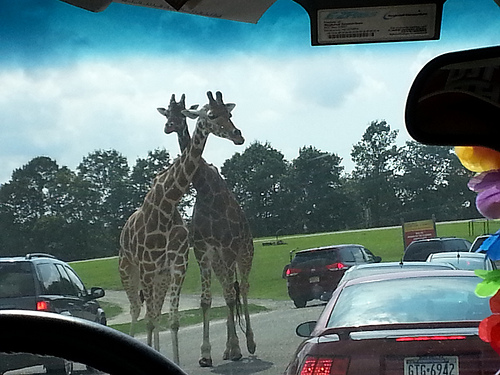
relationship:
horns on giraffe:
[202, 89, 214, 104] [117, 90, 248, 367]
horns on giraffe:
[212, 89, 223, 106] [117, 90, 248, 367]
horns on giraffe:
[165, 93, 176, 108] [158, 93, 256, 365]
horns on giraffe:
[177, 92, 187, 105] [158, 93, 256, 365]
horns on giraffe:
[204, 89, 215, 104] [161, 98, 281, 363]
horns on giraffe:
[180, 94, 188, 106] [126, 88, 246, 349]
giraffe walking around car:
[147, 103, 247, 208] [312, 267, 499, 369]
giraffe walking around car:
[158, 93, 258, 365] [312, 267, 499, 369]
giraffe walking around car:
[147, 103, 247, 208] [3, 250, 108, 349]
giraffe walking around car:
[158, 93, 258, 365] [3, 250, 108, 349]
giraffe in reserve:
[117, 90, 248, 367] [31, 86, 471, 305]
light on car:
[285, 266, 291, 275] [284, 242, 390, 303]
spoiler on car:
[317, 322, 486, 341] [282, 268, 497, 373]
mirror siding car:
[372, 255, 382, 262] [325, 277, 497, 373]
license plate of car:
[401, 350, 463, 374] [277, 256, 498, 374]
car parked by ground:
[285, 241, 384, 308] [119, 297, 332, 375]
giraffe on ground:
[158, 93, 256, 365] [119, 297, 332, 375]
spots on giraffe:
[140, 220, 185, 270] [117, 90, 248, 367]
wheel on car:
[280, 289, 314, 319] [276, 207, 391, 311]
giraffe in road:
[158, 93, 258, 365] [218, 320, 290, 367]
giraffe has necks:
[117, 90, 248, 367] [145, 130, 229, 205]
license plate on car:
[401, 350, 463, 374] [282, 260, 498, 367]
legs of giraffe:
[121, 285, 181, 367] [117, 90, 248, 367]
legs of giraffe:
[195, 259, 259, 366] [158, 93, 256, 365]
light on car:
[299, 353, 339, 371] [292, 258, 499, 372]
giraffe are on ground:
[117, 90, 248, 367] [119, 297, 332, 375]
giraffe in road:
[158, 93, 258, 365] [98, 290, 324, 369]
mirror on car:
[88, 287, 105, 299] [3, 253, 106, 326]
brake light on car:
[328, 260, 345, 270] [284, 242, 390, 303]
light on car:
[35, 298, 50, 312] [3, 253, 106, 326]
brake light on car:
[395, 334, 465, 342] [282, 268, 497, 373]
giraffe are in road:
[117, 90, 248, 367] [98, 290, 324, 369]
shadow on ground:
[216, 356, 272, 373] [207, 320, 290, 373]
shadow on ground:
[216, 356, 272, 373] [203, 322, 286, 373]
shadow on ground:
[216, 356, 272, 373] [196, 321, 289, 371]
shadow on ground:
[216, 356, 272, 373] [193, 317, 287, 372]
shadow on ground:
[216, 356, 272, 373] [185, 316, 290, 373]